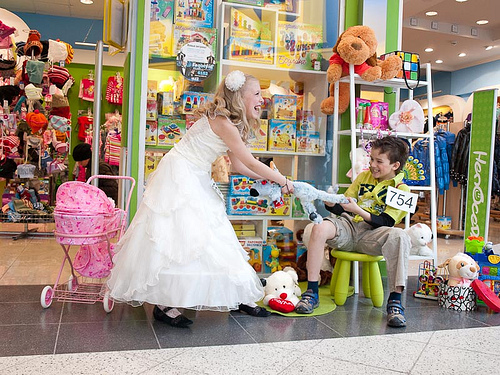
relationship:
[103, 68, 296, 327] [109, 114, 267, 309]
girl wearing dress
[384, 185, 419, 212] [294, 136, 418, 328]
number 754 on boy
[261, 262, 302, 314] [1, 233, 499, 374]
bear on floor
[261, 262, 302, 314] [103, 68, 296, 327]
bear next to girl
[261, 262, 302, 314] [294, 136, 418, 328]
bear next to boy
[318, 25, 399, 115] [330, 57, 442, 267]
stuffed animal on shelf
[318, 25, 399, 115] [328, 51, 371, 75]
stuffed animal wearing shirt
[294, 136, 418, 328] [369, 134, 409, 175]
boy has hair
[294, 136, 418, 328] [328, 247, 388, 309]
boy sitting on stool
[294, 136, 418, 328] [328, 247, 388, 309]
boy on stool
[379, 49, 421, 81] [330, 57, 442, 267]
rubix cube on shelf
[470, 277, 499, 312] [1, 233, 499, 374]
lid on floor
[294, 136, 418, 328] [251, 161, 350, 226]
boy playing with toy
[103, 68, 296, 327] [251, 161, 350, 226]
girl playing with toy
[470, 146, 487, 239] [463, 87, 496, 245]
letters on sign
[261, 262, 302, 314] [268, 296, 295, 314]
bear has heart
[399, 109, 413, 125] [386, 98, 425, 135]
flower on box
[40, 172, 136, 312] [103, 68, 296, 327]
toy stroller behind girl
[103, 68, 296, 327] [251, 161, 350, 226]
girl holding toy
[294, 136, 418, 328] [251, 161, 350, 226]
boy holding toy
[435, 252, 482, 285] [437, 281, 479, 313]
toy in hat box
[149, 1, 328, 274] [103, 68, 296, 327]
toys behind girl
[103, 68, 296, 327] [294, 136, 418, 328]
girl playing with boy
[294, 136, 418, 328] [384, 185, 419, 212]
boy wearing number 754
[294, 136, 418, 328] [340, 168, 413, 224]
boy wearing shirt